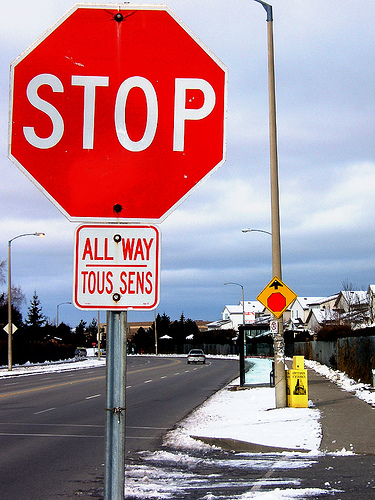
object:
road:
[4, 355, 374, 499]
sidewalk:
[255, 355, 375, 455]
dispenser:
[286, 355, 309, 408]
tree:
[324, 276, 374, 335]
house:
[331, 291, 366, 319]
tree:
[25, 288, 48, 328]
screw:
[114, 11, 125, 22]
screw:
[113, 204, 122, 213]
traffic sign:
[254, 272, 299, 320]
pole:
[264, 4, 287, 410]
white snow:
[222, 282, 374, 333]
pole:
[104, 311, 126, 499]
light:
[240, 226, 272, 236]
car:
[186, 348, 206, 365]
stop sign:
[7, 3, 229, 227]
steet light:
[32, 229, 47, 239]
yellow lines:
[0, 355, 180, 399]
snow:
[322, 441, 359, 460]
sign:
[71, 222, 160, 313]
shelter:
[363, 282, 374, 313]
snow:
[180, 352, 322, 453]